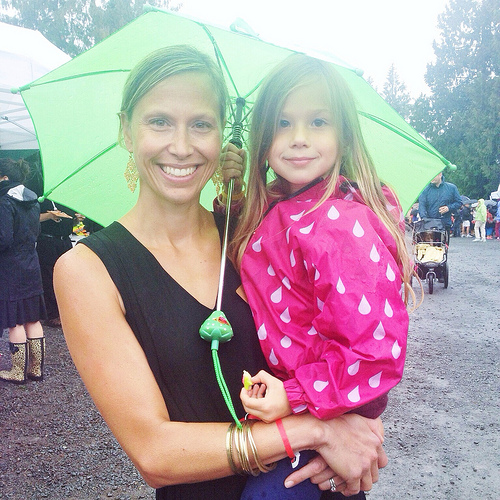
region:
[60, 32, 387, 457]
a woman hodling a young girl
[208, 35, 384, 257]
a young girl holding a umbrella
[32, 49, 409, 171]
a green umbrella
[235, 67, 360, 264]
a young girl with blonde hair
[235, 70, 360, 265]
a young girl with long hair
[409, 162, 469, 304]
a man pushing a stroller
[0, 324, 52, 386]
a woman wearing rubber boots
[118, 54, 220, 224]
a woman wearing ear rings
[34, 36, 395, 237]
a woman and young girl under a umbrella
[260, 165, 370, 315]
a young girl wearing a pink and white rain coat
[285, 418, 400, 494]
woman wearing silver wedding rings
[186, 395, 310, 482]
woman wearing gold bracelets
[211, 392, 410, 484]
woman wearing red band on wrist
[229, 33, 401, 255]
little girl with long blond hair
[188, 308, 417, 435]
hand holding piece of food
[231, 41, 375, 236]
little girl smiling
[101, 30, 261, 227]
adult lady smiling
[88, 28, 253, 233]
woman wearing gold earrings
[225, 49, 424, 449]
little girl wearing ping rain jacket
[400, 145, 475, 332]
man pushing a baby stroller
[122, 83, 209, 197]
face of the girl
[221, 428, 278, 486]
bangles wearing by girl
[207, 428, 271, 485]
bangles to the hand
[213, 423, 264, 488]
a group of bangles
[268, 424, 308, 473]
a red band to hand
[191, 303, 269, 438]
buttom part of the umbrella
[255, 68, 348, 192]
face of the cute girl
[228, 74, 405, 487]
a girl in hand of women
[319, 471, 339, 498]
a ring to the finger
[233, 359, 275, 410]
a cute girl holding eating item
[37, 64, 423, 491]
woman holding a child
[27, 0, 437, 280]
child holding a green umbrella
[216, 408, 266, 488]
gold bracelets around woman's wrist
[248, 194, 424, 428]
girl wearing a pink rain jacket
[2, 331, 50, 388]
leopared print rain boots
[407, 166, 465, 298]
man pushing a baby carriage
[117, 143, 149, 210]
woman wearing dangling gold earrings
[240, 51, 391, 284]
child with long blondeha hair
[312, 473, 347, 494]
wedding rings on finger of right hand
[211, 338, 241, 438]
green umbrella strap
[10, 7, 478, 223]
the umbrella is green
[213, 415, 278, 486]
the bracelets are gold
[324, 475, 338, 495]
the ring is silver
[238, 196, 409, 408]
the coat is pink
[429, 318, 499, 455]
the ground is gray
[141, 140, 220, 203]
the woman is smiling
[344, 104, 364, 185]
the childs hair is blonde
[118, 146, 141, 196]
the woman is wearing an earring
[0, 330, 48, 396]
the boots are black and tan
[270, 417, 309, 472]
the bracelet is red